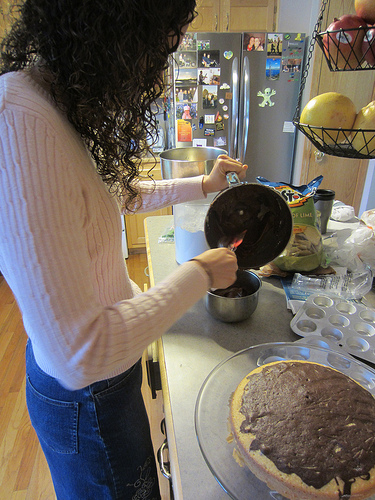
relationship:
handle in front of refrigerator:
[228, 56, 255, 163] [147, 32, 308, 186]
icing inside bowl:
[213, 279, 258, 297] [207, 269, 263, 321]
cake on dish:
[232, 359, 374, 498] [195, 344, 373, 499]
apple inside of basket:
[320, 16, 367, 69] [293, 122, 374, 157]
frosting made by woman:
[204, 185, 293, 273] [0, 3, 241, 498]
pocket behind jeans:
[24, 379, 80, 459] [22, 340, 161, 499]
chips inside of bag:
[281, 224, 322, 254] [258, 176, 329, 275]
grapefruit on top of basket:
[352, 100, 373, 158] [293, 122, 374, 157]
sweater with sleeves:
[3, 53, 210, 392] [0, 108, 213, 391]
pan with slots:
[287, 290, 373, 369] [299, 297, 373, 355]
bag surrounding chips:
[258, 176, 329, 275] [281, 224, 322, 254]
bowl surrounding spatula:
[203, 172, 293, 270] [229, 229, 248, 254]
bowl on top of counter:
[207, 269, 263, 321] [143, 209, 373, 499]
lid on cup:
[311, 189, 334, 201] [312, 187, 334, 234]